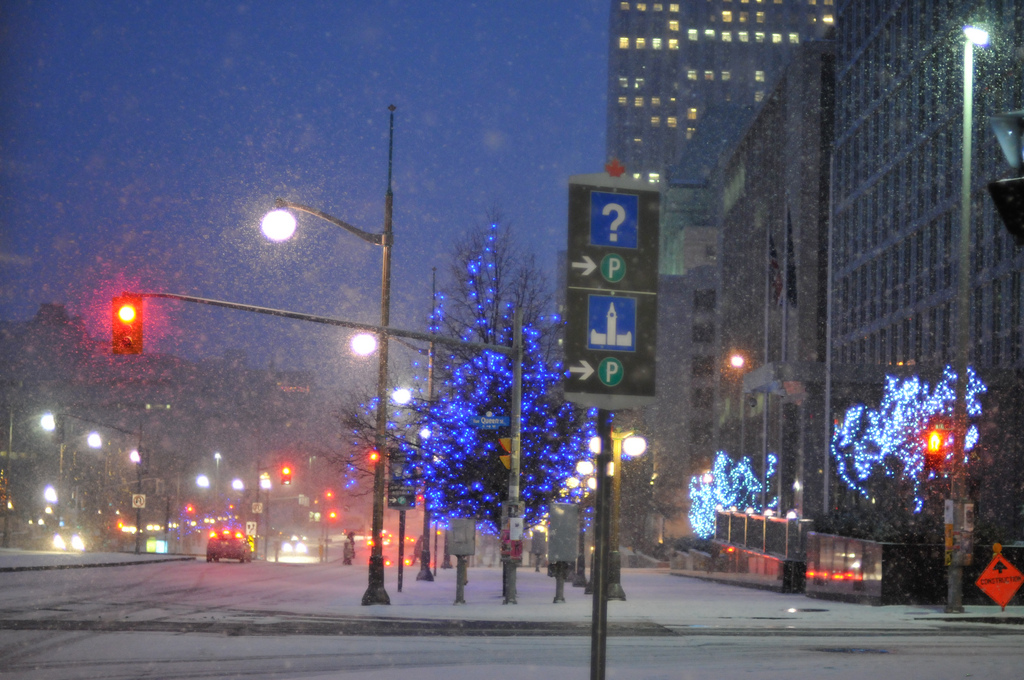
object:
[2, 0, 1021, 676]
city street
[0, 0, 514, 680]
snow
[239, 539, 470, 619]
sidewalk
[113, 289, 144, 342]
light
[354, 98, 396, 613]
pole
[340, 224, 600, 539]
lights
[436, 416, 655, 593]
lights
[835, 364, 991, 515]
tree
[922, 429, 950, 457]
light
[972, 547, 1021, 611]
sign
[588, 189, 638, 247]
sign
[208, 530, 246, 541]
lights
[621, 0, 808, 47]
windows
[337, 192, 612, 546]
christmas lights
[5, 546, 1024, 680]
snow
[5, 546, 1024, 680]
road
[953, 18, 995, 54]
lamp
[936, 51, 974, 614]
post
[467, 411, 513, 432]
sign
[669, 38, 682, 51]
window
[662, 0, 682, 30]
window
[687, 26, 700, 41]
window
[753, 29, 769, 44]
window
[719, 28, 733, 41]
window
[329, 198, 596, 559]
tree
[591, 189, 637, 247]
question mark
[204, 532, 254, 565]
car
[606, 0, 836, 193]
building